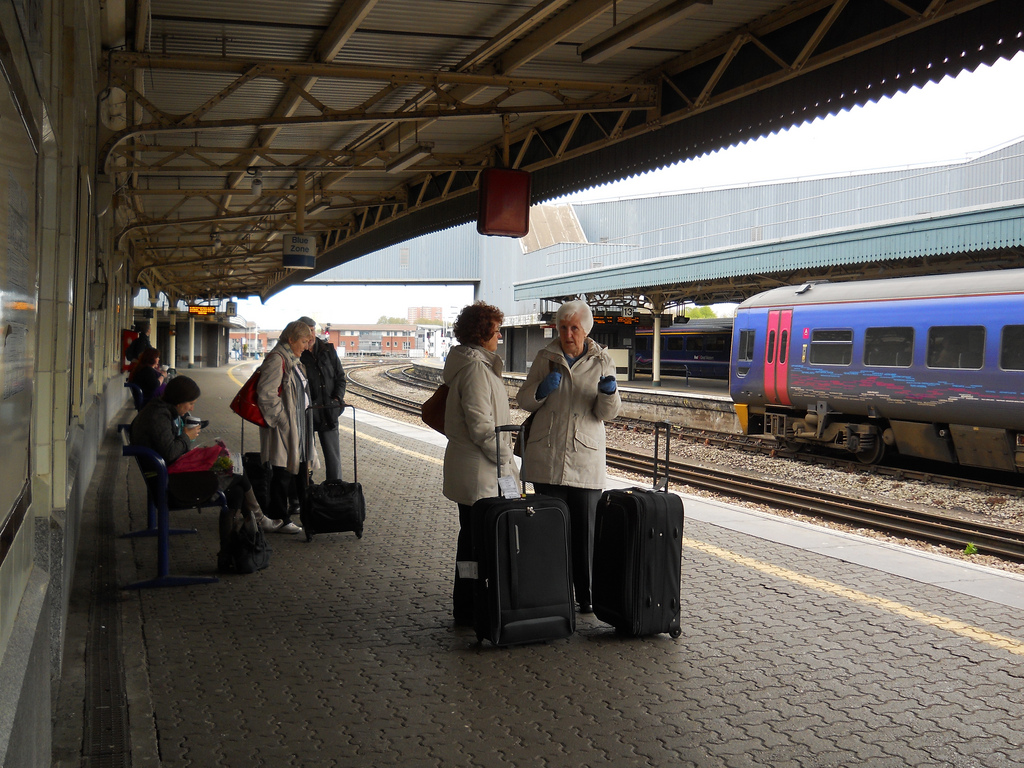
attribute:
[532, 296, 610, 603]
person — standing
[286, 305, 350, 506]
person — standing up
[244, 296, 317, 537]
person — standing up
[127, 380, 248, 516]
person — sitting down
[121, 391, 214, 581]
bench — blue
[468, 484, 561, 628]
suitcase — black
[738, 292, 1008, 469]
train — blue, red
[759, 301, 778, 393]
doors — red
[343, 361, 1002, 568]
tracks — brown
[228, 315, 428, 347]
building — red